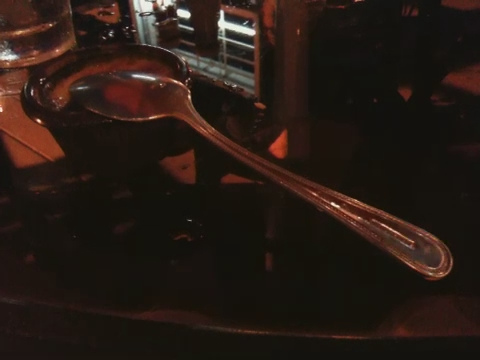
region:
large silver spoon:
[93, 6, 448, 306]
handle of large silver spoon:
[182, 115, 437, 305]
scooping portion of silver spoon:
[63, 59, 188, 137]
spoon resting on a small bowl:
[28, 27, 416, 318]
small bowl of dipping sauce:
[38, 29, 184, 157]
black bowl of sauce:
[16, 45, 194, 165]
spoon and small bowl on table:
[75, 54, 421, 302]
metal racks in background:
[208, 21, 261, 86]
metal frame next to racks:
[240, 23, 276, 113]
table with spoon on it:
[20, 39, 399, 322]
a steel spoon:
[70, 58, 458, 297]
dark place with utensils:
[20, 15, 438, 342]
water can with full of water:
[1, 0, 64, 89]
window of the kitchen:
[144, 0, 263, 85]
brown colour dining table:
[55, 248, 471, 358]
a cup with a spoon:
[11, 28, 233, 166]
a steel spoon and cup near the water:
[16, 15, 452, 299]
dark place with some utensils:
[27, 28, 464, 326]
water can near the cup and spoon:
[7, 4, 180, 143]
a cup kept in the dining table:
[22, 10, 277, 276]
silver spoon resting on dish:
[81, 58, 451, 297]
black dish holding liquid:
[21, 33, 189, 161]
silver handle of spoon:
[188, 111, 454, 284]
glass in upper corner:
[4, 3, 81, 73]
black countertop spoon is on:
[4, 84, 476, 342]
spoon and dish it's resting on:
[18, 34, 457, 288]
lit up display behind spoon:
[129, 1, 277, 115]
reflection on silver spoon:
[89, 73, 185, 122]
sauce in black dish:
[43, 54, 166, 122]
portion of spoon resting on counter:
[321, 188, 462, 284]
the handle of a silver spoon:
[186, 102, 450, 279]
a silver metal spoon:
[74, 63, 450, 278]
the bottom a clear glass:
[2, 1, 74, 66]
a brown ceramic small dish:
[22, 42, 190, 118]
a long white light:
[143, 1, 261, 41]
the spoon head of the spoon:
[71, 73, 186, 122]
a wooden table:
[2, 42, 219, 195]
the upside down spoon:
[69, 69, 450, 280]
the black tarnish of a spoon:
[69, 73, 180, 115]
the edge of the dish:
[19, 74, 121, 130]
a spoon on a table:
[65, 31, 470, 282]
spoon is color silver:
[62, 35, 462, 281]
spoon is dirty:
[67, 31, 466, 285]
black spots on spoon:
[46, 32, 196, 130]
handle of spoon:
[194, 111, 458, 289]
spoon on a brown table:
[0, 32, 476, 328]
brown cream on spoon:
[42, 50, 166, 121]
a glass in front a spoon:
[0, 0, 87, 73]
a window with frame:
[135, 6, 268, 99]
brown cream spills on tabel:
[29, 62, 98, 131]